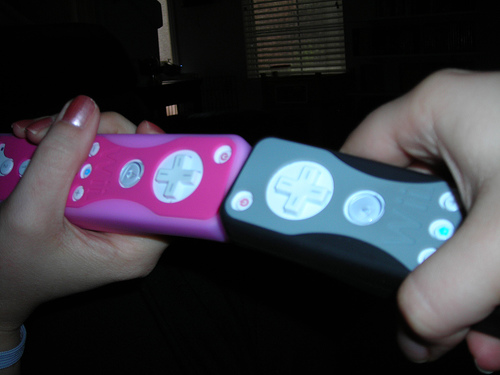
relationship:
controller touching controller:
[1, 128, 254, 251] [217, 130, 500, 344]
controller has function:
[1, 128, 254, 251] [150, 147, 208, 207]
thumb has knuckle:
[391, 174, 500, 365] [390, 269, 456, 348]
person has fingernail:
[0, 91, 177, 374] [61, 93, 98, 135]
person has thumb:
[0, 91, 177, 374] [2, 86, 107, 255]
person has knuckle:
[0, 91, 177, 374] [25, 142, 82, 187]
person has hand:
[0, 91, 177, 374] [2, 92, 175, 292]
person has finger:
[0, 91, 177, 374] [116, 112, 173, 283]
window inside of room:
[230, 1, 367, 96] [2, 1, 499, 374]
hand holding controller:
[2, 92, 175, 292] [1, 128, 254, 251]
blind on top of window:
[237, 1, 352, 78] [230, 1, 367, 96]